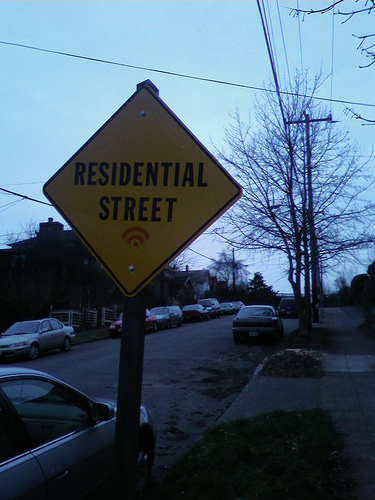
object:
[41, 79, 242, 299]
sign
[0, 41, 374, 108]
lines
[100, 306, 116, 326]
fence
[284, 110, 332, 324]
post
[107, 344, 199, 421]
drive way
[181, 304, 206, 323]
cars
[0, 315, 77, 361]
car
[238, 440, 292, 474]
grass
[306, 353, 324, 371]
leaves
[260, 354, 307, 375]
grass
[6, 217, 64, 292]
houses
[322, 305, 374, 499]
sidewalk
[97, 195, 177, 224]
words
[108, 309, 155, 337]
car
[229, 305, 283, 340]
car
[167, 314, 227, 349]
street